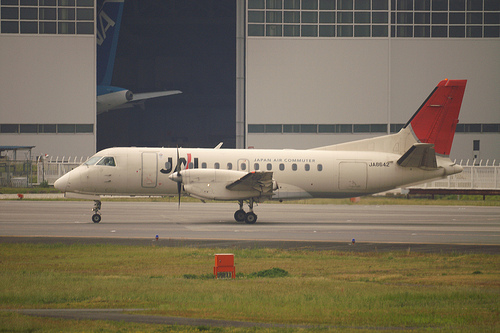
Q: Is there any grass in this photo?
A: Yes, there is grass.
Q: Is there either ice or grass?
A: Yes, there is grass.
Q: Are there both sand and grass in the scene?
A: No, there is grass but no sand.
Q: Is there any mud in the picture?
A: No, there is no mud.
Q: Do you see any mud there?
A: No, there is no mud.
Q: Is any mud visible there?
A: No, there is no mud.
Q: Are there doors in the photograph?
A: Yes, there is a door.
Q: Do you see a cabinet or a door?
A: Yes, there is a door.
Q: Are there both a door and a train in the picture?
A: No, there is a door but no trains.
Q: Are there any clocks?
A: No, there are no clocks.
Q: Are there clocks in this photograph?
A: No, there are no clocks.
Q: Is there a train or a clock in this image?
A: No, there are no clocks or trains.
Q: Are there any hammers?
A: No, there are no hammers.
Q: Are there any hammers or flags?
A: No, there are no hammers or flags.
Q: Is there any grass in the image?
A: Yes, there is grass.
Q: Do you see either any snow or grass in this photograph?
A: Yes, there is grass.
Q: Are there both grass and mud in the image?
A: No, there is grass but no mud.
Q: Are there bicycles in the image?
A: No, there are no bicycles.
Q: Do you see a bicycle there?
A: No, there are no bicycles.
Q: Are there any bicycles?
A: No, there are no bicycles.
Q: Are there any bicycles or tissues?
A: No, there are no bicycles or tissues.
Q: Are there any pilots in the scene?
A: No, there are no pilots.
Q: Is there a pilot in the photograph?
A: No, there are no pilots.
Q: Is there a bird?
A: No, there are no birds.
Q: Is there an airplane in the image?
A: Yes, there is an airplane.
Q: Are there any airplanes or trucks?
A: Yes, there is an airplane.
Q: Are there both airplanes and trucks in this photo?
A: No, there is an airplane but no trucks.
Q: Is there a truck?
A: No, there are no trucks.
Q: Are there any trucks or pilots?
A: No, there are no trucks or pilots.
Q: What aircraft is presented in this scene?
A: The aircraft is an airplane.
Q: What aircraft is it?
A: The aircraft is an airplane.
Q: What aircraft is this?
A: This is an airplane.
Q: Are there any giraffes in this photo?
A: No, there are no giraffes.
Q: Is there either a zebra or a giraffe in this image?
A: No, there are no giraffes or zebras.